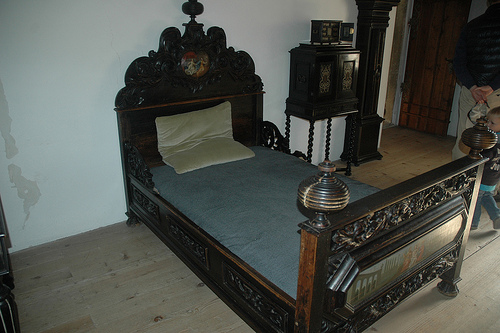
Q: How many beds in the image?
A: One.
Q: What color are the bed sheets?
A: Blue.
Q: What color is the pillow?
A: Light brown.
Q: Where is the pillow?
A: On the bed.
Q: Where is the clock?
A: Next to the door.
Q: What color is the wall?
A: White.